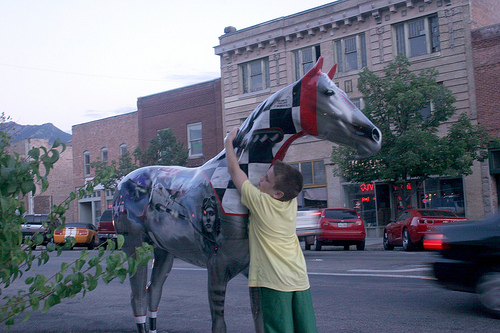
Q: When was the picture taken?
A: Daytime.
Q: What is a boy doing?
A: Hugging a horse.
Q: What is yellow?
A: Boy's shirt.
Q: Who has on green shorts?
A: The boy.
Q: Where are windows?
A: On buildings.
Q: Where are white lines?
A: On the street.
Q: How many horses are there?
A: One.